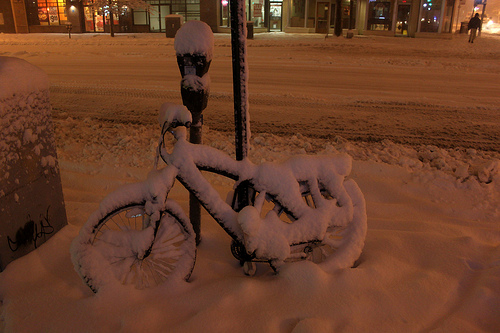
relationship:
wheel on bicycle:
[76, 193, 191, 325] [75, 89, 417, 249]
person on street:
[468, 13, 484, 44] [2, 30, 497, 147]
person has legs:
[464, 12, 481, 44] [465, 27, 479, 42]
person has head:
[468, 13, 484, 44] [469, 9, 486, 19]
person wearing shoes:
[468, 13, 484, 44] [465, 39, 476, 45]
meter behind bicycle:
[168, 17, 216, 242] [70, 103, 367, 299]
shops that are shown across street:
[8, 2, 486, 34] [2, 30, 497, 147]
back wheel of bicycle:
[247, 164, 370, 275] [70, 103, 367, 299]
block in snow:
[0, 54, 70, 272] [0, 55, 52, 105]